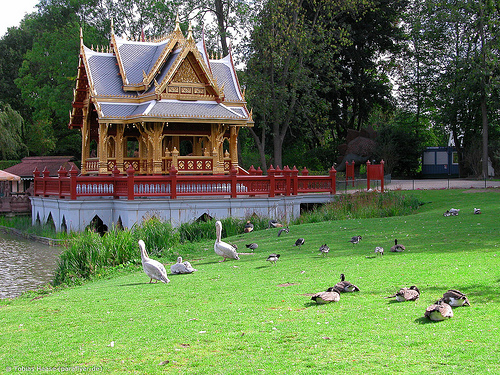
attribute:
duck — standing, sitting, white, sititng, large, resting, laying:
[306, 230, 430, 333]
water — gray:
[14, 241, 62, 270]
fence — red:
[114, 160, 275, 183]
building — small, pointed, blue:
[421, 141, 485, 187]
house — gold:
[64, 36, 253, 176]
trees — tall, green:
[248, 18, 401, 144]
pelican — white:
[121, 225, 243, 317]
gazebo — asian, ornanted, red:
[78, 14, 261, 146]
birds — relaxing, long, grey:
[238, 209, 433, 371]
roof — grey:
[112, 21, 207, 106]